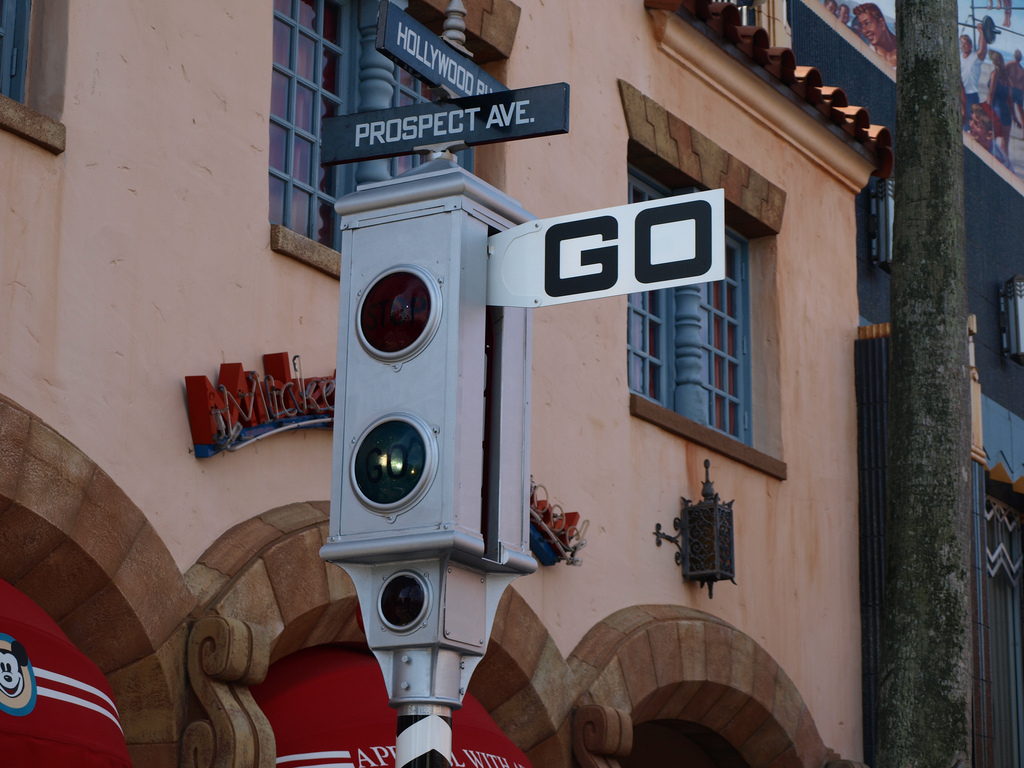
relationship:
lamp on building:
[671, 480, 741, 597] [0, 4, 895, 766]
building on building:
[0, 0, 893, 768] [0, 4, 895, 766]